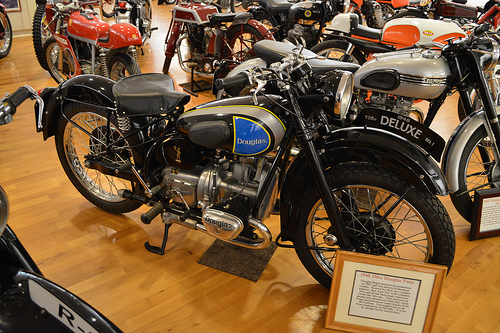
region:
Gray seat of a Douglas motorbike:
[112, 72, 190, 114]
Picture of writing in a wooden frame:
[318, 242, 450, 332]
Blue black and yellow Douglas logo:
[234, 117, 272, 159]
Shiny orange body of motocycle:
[59, 9, 144, 49]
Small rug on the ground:
[195, 230, 280, 282]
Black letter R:
[53, 306, 78, 325]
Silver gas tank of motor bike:
[359, 38, 454, 103]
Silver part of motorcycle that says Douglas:
[199, 207, 239, 239]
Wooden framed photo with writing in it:
[317, 246, 448, 332]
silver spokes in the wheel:
[320, 193, 427, 261]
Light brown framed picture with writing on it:
[325, 249, 451, 332]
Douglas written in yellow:
[236, 137, 272, 146]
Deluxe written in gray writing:
[380, 114, 423, 142]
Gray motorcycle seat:
[111, 72, 190, 112]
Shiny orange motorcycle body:
[60, 5, 141, 48]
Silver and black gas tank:
[357, 39, 448, 96]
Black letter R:
[57, 297, 74, 327]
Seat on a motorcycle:
[330, 8, 388, 45]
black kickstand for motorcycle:
[142, 219, 172, 255]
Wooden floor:
[94, 253, 184, 324]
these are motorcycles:
[61, 10, 471, 235]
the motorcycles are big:
[57, 40, 467, 236]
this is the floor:
[75, 234, 144, 289]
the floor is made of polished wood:
[171, 252, 207, 320]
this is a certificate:
[335, 265, 425, 315]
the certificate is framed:
[327, 247, 442, 329]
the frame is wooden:
[430, 278, 435, 328]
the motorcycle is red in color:
[70, 10, 140, 46]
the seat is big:
[115, 66, 186, 106]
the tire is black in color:
[424, 212, 456, 262]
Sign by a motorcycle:
[321, 241, 486, 320]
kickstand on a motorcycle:
[118, 204, 203, 268]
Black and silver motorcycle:
[23, 56, 472, 299]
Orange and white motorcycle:
[322, 1, 487, 84]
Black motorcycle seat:
[81, 68, 200, 123]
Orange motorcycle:
[38, 11, 154, 72]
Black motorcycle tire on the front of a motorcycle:
[280, 142, 452, 288]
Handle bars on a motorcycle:
[198, 26, 366, 121]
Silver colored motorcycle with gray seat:
[227, 27, 497, 133]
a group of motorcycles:
[23, 11, 479, 271]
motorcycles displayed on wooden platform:
[28, 12, 485, 310]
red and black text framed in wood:
[287, 232, 457, 324]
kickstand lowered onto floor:
[110, 212, 200, 262]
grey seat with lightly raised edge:
[110, 60, 195, 125]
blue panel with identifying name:
[225, 105, 270, 161]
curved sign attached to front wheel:
[345, 90, 460, 165]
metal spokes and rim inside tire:
[55, 105, 135, 190]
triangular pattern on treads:
[415, 180, 460, 265]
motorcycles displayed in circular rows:
[50, 11, 490, 261]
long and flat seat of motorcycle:
[251, 27, 366, 79]